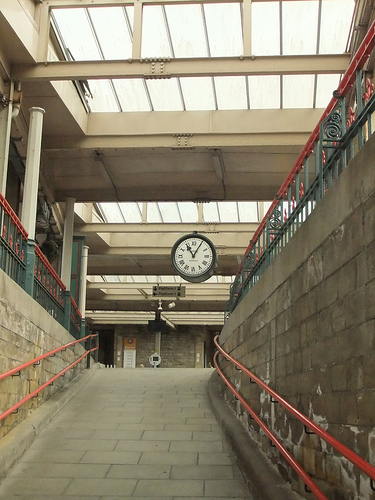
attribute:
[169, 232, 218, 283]
clock — hanging, white, black, large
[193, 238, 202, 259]
arrows — black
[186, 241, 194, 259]
arrows — black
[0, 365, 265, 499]
ramp — concrete, brick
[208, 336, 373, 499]
rails — red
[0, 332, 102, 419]
rails — red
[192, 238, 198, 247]
number — roman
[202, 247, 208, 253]
number — roman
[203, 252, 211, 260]
number — roman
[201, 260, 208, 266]
number — roman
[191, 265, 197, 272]
number — roman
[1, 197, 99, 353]
fence — iron, green, metal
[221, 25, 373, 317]
fence — green, metal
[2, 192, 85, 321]
rails — red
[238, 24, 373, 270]
rails — red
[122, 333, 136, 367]
sign — white, orange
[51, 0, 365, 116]
windows — skylights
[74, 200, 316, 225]
windows — skylights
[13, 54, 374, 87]
beams — tan, steel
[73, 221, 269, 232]
beams — steel, tan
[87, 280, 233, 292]
beams — tan, steel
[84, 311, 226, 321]
beams — tan, steel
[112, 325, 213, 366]
wall — stone, concrete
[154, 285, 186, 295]
sign — black, white, hanging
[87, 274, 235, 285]
windows — skylights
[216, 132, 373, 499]
wall — stone, concrete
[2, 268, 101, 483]
wall — stone, concrete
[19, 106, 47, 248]
column — supporting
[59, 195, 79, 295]
column — supporting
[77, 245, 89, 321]
column — supporting